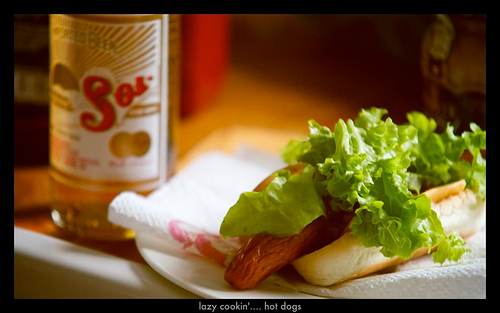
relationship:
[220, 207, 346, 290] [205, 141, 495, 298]
hot dog inside bun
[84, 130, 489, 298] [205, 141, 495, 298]
napkin under bre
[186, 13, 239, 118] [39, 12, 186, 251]
object behind glass bottle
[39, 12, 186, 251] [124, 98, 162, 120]
bottle has word beer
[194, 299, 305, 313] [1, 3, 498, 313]
letters on bottom of picture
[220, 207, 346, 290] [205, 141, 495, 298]
hot dog on bun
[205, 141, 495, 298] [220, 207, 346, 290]
bun for hot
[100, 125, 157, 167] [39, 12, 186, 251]
symbol on beer bottle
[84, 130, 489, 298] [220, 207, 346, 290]
napkin under hot dog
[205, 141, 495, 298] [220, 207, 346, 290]
plate for hot dog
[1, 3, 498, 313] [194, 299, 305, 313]
picture has text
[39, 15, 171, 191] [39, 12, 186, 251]
label on beer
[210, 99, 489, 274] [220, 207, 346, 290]
lettuce on hot dog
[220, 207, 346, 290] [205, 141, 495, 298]
hot dog in a bun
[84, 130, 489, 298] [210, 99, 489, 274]
plate has food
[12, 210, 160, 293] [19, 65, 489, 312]
paper on table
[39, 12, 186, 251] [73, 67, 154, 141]
bottle of beer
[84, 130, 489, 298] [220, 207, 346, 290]
paper towel under hot dog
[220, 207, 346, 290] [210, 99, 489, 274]
hot dog with garnish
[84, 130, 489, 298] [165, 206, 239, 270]
napkin has red designs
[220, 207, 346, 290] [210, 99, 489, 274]
hot dog with lettuce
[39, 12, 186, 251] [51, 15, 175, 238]
bottle full with liquid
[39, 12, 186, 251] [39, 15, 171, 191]
bottle has label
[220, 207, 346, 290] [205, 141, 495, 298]
hot dog sticking out bun